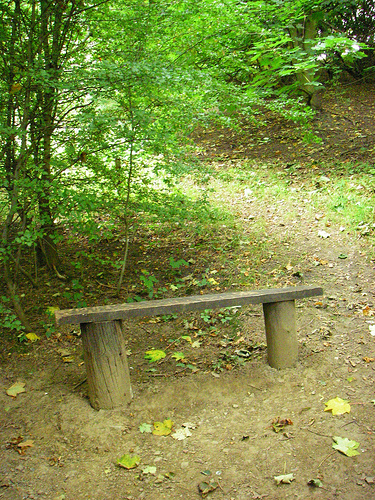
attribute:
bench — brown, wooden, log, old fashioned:
[54, 285, 325, 409]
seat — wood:
[54, 283, 325, 324]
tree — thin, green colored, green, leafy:
[2, 0, 355, 347]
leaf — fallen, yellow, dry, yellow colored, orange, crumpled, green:
[115, 451, 142, 467]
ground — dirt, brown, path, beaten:
[4, 67, 374, 499]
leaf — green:
[167, 258, 183, 271]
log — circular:
[83, 319, 132, 416]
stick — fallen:
[93, 272, 145, 298]